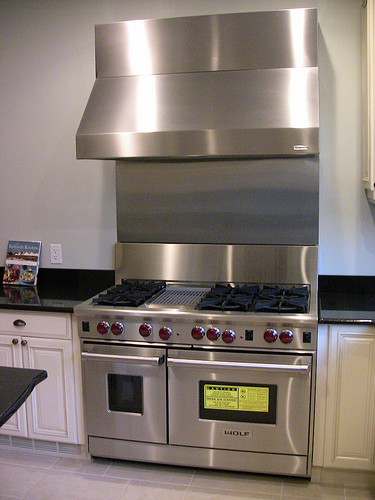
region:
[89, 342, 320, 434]
two ovens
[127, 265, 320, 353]
six gas burners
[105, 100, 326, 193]
stainless steel hood vent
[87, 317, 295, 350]
nine red dials on the stove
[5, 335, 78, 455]
white cabinets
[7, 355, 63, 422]
black kitchen counter tops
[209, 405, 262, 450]
brand of the oven is WOLF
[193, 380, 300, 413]
yellow sticker on the glass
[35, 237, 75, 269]
electric outlet on the wall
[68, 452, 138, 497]
tiles on the floor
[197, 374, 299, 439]
Yellow and black sticker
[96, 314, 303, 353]
Many round knobs on oven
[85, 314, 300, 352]
The knobs are red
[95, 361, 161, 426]
Black window on front of oven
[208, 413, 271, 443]
Black letters on oven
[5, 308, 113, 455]
The cabinets are white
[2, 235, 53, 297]
Book leaning against the wall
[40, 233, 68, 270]
White outlet on wall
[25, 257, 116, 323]
The counter top is black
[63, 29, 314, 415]
The oven and stove are silver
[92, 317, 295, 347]
A bunch of knobs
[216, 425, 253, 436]
The word Wolf on an oven door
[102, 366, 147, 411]
A small oven window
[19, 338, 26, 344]
A kitchen door knob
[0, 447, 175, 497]
Part of a tile floor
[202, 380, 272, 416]
A yellow instruction lable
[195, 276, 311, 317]
Four range stovetop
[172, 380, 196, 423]
Chrome finish on an oven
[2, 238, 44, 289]
A cook book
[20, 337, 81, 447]
A white cabinet door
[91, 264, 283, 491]
Shiny silver oven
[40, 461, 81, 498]
A tiled floor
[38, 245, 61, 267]
A white plug outlet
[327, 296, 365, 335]
Black surface of a kitchen counter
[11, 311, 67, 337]
White wooden drawer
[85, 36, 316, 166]
A metal heat, smoke vent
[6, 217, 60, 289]
A cook book leaning against a wall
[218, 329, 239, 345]
Red temperature dial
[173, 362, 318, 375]
Metal hand for oven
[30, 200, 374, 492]
This is a picture of a kitchen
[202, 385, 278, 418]
yellow and black sign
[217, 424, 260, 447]
black and silver logo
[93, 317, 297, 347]
several knobs all in a row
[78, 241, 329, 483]
shiny new oven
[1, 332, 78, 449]
white cabinets with small dark knobs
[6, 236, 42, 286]
cook book propped up against a wall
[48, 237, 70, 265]
white outlet on the wall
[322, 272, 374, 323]
black countertop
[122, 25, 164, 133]
light shining on the metal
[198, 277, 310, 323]
four black burners on top of the stove